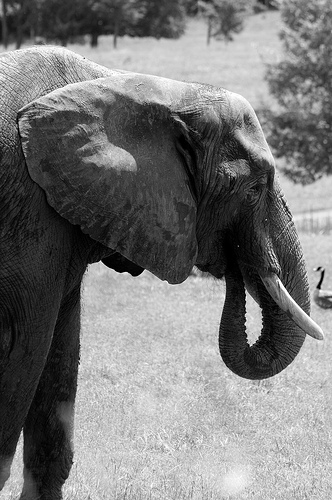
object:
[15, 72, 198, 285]
ear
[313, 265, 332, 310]
fowl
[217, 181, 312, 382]
trunk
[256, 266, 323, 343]
tusk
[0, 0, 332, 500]
field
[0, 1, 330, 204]
trees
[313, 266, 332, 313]
bird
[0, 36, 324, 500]
elephant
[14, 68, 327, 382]
head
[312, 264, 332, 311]
goose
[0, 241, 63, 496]
front leg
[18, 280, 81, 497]
front leg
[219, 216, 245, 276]
elephant's mouth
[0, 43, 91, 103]
hump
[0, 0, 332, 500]
grass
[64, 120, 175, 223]
skin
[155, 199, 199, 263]
mud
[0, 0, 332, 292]
background